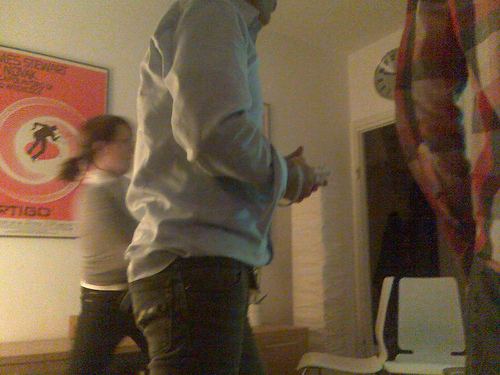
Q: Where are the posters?
A: On wall.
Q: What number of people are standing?
A: Three.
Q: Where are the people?
A: In a room.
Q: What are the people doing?
A: Playing video games.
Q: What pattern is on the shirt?
A: Plaid.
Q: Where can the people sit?
A: In the chairs.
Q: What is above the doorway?
A: A clock.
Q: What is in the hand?
A: A wii remote.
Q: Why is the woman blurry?
A: She is moving.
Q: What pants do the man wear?
A: Jeans.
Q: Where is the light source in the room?
A: Behind the people.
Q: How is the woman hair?
A: In a ponytail.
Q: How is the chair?
A: Empty.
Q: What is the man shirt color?
A: White.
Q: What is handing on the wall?
A: A poster.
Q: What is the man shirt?
A: Plaid.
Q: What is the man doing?
A: Standing.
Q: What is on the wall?
A: Movie poster.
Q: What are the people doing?
A: Playing.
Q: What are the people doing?
A: Playing.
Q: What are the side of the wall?
A: Art.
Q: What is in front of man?
A: Chairs.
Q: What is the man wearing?
A: Shirt.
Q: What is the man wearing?
A: Pant.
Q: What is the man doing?
A: Playing.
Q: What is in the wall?
A: Picture.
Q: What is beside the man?
A: Chairs.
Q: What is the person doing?
A: Watching.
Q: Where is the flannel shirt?
A: On the right man.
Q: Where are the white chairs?
A: By the doorway.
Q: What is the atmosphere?
A: Playful.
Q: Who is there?
A: Young adults.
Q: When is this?
A: Playtime.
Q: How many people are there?
A: 3.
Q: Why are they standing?
A: Playing.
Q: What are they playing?
A: Video games.